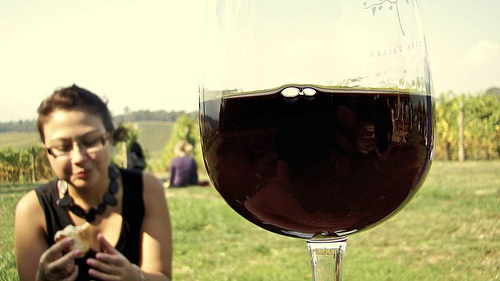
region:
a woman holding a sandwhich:
[8, 80, 168, 279]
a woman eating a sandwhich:
[6, 88, 178, 278]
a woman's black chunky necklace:
[48, 175, 128, 221]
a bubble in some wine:
[275, 84, 320, 100]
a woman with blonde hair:
[166, 136, 201, 192]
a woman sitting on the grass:
[162, 138, 202, 189]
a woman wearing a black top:
[7, 79, 173, 275]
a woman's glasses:
[48, 129, 108, 162]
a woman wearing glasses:
[13, 85, 173, 279]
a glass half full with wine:
[180, 0, 445, 279]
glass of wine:
[194, 10, 436, 277]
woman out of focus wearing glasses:
[36, 72, 126, 200]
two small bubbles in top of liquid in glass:
[270, 78, 327, 105]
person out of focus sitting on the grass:
[159, 129, 209, 191]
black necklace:
[48, 174, 137, 224]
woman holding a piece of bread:
[11, 99, 156, 274]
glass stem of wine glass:
[301, 240, 347, 279]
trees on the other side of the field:
[439, 86, 494, 167]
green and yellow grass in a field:
[417, 214, 495, 276]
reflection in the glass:
[223, 118, 418, 231]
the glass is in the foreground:
[190, 1, 441, 278]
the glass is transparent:
[195, 1, 437, 277]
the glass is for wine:
[198, 1, 438, 278]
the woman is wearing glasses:
[40, 134, 116, 155]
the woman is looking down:
[35, 89, 120, 187]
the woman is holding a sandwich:
[45, 219, 117, 273]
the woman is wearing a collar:
[53, 169, 126, 228]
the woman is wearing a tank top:
[32, 168, 147, 278]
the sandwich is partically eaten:
[54, 218, 100, 260]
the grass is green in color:
[2, 160, 499, 280]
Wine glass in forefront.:
[188, 0, 462, 278]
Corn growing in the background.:
[431, 89, 498, 162]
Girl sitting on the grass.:
[165, 137, 205, 194]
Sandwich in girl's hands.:
[48, 221, 121, 265]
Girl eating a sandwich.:
[14, 86, 180, 279]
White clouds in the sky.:
[450, 30, 499, 75]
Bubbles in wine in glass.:
[267, 81, 329, 100]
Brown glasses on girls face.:
[30, 82, 119, 190]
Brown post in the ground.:
[449, 101, 472, 163]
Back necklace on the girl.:
[25, 89, 137, 233]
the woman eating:
[26, 80, 156, 278]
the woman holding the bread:
[13, 80, 185, 277]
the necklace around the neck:
[44, 173, 124, 221]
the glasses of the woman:
[35, 128, 118, 158]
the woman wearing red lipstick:
[60, 163, 107, 180]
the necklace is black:
[61, 163, 158, 233]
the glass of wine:
[187, 0, 462, 277]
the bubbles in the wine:
[278, 75, 331, 107]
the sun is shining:
[33, 19, 129, 63]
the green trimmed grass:
[426, 222, 473, 265]